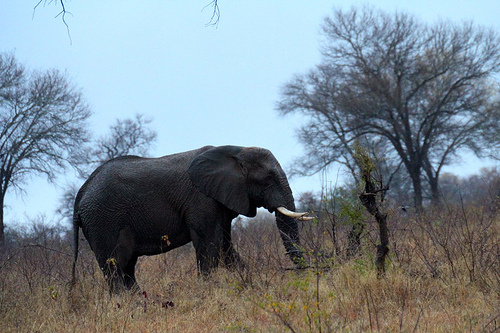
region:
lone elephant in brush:
[65, 135, 317, 312]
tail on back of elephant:
[58, 203, 89, 296]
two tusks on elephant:
[277, 202, 319, 222]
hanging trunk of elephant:
[272, 219, 318, 281]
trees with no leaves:
[330, 33, 466, 157]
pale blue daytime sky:
[160, 45, 247, 95]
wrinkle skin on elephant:
[120, 180, 187, 221]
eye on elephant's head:
[258, 168, 281, 190]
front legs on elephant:
[190, 224, 247, 284]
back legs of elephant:
[93, 239, 152, 304]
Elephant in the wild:
[48, 108, 203, 300]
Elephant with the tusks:
[185, 107, 406, 324]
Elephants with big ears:
[148, 106, 291, 312]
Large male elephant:
[79, 124, 362, 324]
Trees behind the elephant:
[44, 56, 272, 251]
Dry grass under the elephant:
[120, 268, 219, 319]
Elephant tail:
[37, 126, 132, 318]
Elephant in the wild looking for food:
[224, 160, 334, 311]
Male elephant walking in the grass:
[182, 121, 293, 309]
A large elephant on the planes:
[52, 120, 339, 321]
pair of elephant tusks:
[271, 204, 314, 224]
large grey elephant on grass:
[66, 149, 303, 281]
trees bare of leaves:
[275, 9, 497, 214]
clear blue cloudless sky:
[67, 15, 314, 105]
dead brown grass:
[325, 249, 484, 324]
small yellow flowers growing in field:
[255, 284, 343, 322]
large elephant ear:
[183, 142, 260, 222]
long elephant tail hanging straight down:
[65, 190, 91, 292]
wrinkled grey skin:
[162, 167, 202, 219]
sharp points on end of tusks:
[300, 204, 316, 224]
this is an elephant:
[60, 141, 290, 303]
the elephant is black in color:
[53, 130, 301, 306]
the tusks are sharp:
[292, 201, 319, 223]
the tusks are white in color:
[293, 203, 313, 224]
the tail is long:
[66, 220, 80, 277]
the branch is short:
[347, 162, 398, 284]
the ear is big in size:
[185, 151, 238, 212]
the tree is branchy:
[309, 24, 491, 157]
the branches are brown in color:
[413, 225, 486, 270]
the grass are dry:
[88, 291, 228, 331]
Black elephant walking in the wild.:
[65, 143, 316, 300]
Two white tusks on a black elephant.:
[274, 203, 317, 225]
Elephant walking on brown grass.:
[3, 144, 493, 331]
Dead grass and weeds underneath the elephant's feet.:
[2, 257, 498, 332]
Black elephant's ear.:
[185, 147, 253, 217]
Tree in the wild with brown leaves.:
[270, 7, 497, 221]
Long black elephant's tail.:
[65, 215, 82, 302]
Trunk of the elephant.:
[272, 209, 310, 287]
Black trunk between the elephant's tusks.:
[277, 205, 316, 267]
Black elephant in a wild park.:
[67, 142, 309, 299]